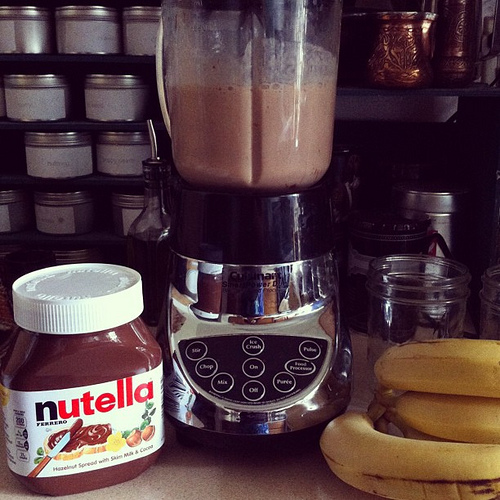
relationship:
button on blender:
[182, 337, 210, 363] [149, 1, 359, 461]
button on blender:
[208, 369, 240, 398] [149, 1, 359, 461]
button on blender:
[239, 354, 268, 381] [149, 1, 359, 461]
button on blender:
[270, 370, 299, 397] [149, 1, 359, 461]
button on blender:
[296, 336, 324, 361] [149, 1, 359, 461]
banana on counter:
[369, 335, 500, 404] [2, 313, 445, 500]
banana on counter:
[367, 379, 499, 452] [2, 313, 445, 500]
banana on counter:
[315, 404, 499, 499] [2, 313, 445, 500]